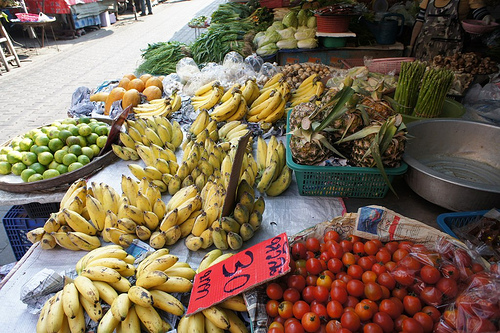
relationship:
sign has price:
[180, 228, 291, 318] [218, 251, 256, 296]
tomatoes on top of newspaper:
[328, 301, 343, 319] [243, 203, 491, 333]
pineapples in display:
[285, 116, 347, 165] [286, 103, 409, 200]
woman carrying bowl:
[408, 0, 497, 63] [460, 16, 499, 35]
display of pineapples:
[286, 103, 409, 200] [285, 116, 347, 165]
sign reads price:
[180, 228, 291, 318] [218, 251, 256, 296]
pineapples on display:
[285, 116, 347, 165] [286, 103, 409, 200]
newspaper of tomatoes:
[243, 203, 491, 333] [328, 301, 343, 319]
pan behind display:
[400, 115, 498, 217] [286, 103, 409, 200]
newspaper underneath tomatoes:
[243, 203, 491, 333] [328, 301, 343, 319]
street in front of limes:
[1, 1, 210, 146] [39, 152, 54, 166]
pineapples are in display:
[285, 116, 347, 165] [286, 103, 409, 200]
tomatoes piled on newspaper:
[328, 301, 343, 319] [243, 203, 491, 333]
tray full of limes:
[2, 115, 122, 193] [39, 152, 54, 166]